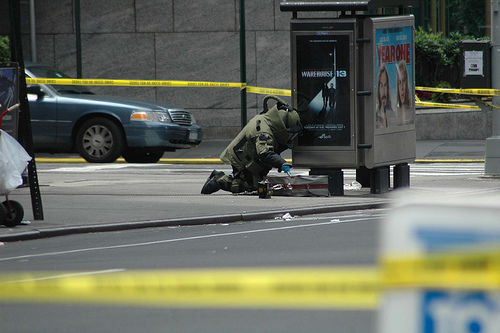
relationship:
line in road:
[115, 217, 359, 239] [9, 192, 431, 277]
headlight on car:
[129, 110, 170, 122] [23, 61, 204, 164]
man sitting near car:
[199, 109, 302, 195] [23, 61, 204, 164]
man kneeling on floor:
[199, 109, 302, 195] [0, 153, 381, 325]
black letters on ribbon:
[32, 80, 284, 91] [25, 77, 291, 96]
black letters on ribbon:
[426, 90, 489, 92] [25, 77, 291, 96]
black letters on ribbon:
[437, 105, 469, 109] [25, 77, 291, 96]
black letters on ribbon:
[11, 279, 359, 296] [25, 77, 291, 96]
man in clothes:
[199, 109, 302, 195] [200, 94, 304, 195]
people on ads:
[376, 60, 408, 110] [374, 21, 413, 129]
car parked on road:
[23, 62, 201, 164] [197, 223, 361, 248]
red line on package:
[266, 185, 330, 188] [266, 175, 331, 193]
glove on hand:
[268, 152, 286, 172] [269, 154, 286, 171]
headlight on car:
[149, 110, 169, 122] [31, 82, 195, 159]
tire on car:
[78, 120, 118, 165] [23, 61, 204, 164]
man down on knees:
[199, 109, 302, 195] [242, 166, 267, 195]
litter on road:
[261, 211, 301, 226] [197, 223, 361, 248]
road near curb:
[197, 223, 361, 248] [14, 177, 396, 244]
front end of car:
[84, 85, 201, 161] [23, 61, 204, 164]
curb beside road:
[2, 175, 399, 251] [197, 223, 361, 248]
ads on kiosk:
[376, 21, 411, 151] [279, 0, 414, 193]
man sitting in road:
[189, 111, 299, 193] [28, 159, 498, 175]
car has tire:
[23, 61, 204, 164] [78, 115, 126, 162]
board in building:
[457, 37, 493, 89] [2, 0, 499, 137]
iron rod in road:
[9, 25, 56, 236] [12, 151, 499, 322]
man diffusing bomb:
[199, 109, 302, 195] [237, 171, 331, 198]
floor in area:
[0, 248, 368, 325] [0, 1, 499, 331]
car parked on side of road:
[23, 61, 204, 164] [28, 159, 483, 175]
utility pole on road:
[482, 0, 499, 175] [28, 159, 483, 175]